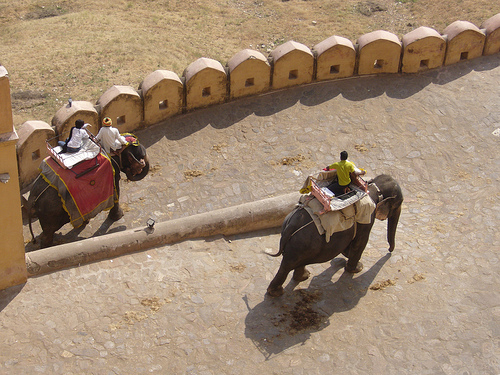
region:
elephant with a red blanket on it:
[20, 117, 149, 247]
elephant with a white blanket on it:
[299, 190, 378, 234]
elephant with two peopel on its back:
[20, 114, 151, 247]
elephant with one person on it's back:
[261, 175, 405, 298]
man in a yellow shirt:
[323, 148, 366, 194]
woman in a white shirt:
[56, 116, 90, 155]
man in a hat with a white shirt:
[91, 116, 123, 153]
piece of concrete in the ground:
[19, 185, 312, 278]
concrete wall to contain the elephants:
[10, 70, 435, 175]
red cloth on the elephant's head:
[107, 130, 137, 157]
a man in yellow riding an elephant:
[261, 143, 403, 298]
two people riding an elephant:
[20, 124, 165, 227]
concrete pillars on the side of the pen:
[175, 29, 491, 73]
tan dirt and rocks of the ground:
[69, 284, 241, 366]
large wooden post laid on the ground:
[45, 216, 259, 271]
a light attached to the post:
[136, 219, 162, 236]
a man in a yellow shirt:
[323, 148, 369, 195]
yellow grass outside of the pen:
[31, 9, 198, 71]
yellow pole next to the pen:
[3, 75, 27, 285]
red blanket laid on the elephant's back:
[43, 154, 118, 207]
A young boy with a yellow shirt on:
[261, 146, 408, 303]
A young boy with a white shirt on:
[53, 113, 121, 177]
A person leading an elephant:
[24, 111, 154, 251]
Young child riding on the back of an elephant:
[256, 133, 418, 310]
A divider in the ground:
[31, 206, 283, 273]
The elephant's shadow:
[237, 262, 383, 354]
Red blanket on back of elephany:
[41, 155, 128, 220]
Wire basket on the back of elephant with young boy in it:
[52, 108, 111, 163]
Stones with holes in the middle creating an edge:
[148, 22, 497, 123]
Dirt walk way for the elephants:
[406, 85, 497, 322]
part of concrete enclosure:
[186, 68, 230, 103]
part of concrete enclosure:
[225, 44, 267, 100]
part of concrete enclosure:
[144, 71, 183, 119]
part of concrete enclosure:
[268, 46, 303, 86]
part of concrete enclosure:
[357, 30, 397, 74]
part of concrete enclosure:
[310, 35, 367, 83]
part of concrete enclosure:
[406, 32, 443, 72]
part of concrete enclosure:
[444, 17, 482, 68]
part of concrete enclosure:
[22, 118, 58, 168]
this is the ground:
[87, 5, 156, 57]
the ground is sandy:
[109, 5, 221, 55]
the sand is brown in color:
[107, 5, 169, 51]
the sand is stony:
[122, 10, 202, 47]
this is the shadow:
[232, 87, 413, 113]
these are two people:
[61, 116, 123, 151]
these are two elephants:
[23, 158, 401, 303]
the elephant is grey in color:
[31, 189, 47, 205]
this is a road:
[96, 286, 221, 363]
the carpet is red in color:
[76, 185, 85, 193]